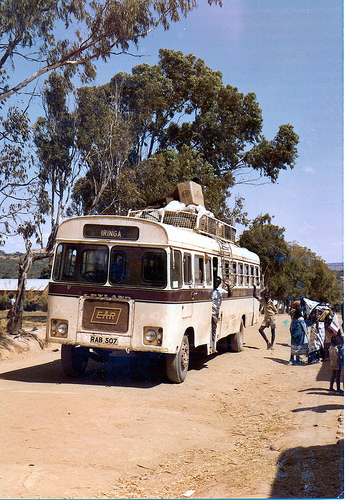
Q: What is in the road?
A: Bus.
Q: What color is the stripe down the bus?
A: Brown.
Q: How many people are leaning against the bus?
A: One.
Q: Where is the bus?
A: Dirt road.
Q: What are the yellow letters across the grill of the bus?
A: EAR.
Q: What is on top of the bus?
A: Luggage.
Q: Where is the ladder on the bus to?
A: Luggage rack.